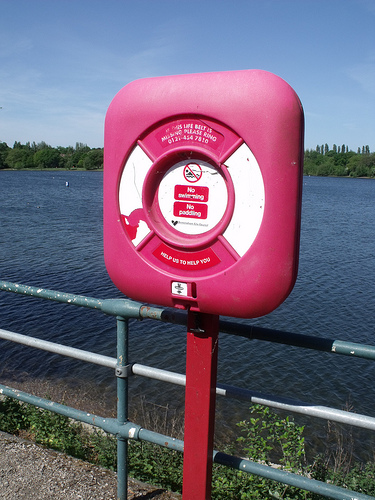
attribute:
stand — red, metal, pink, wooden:
[183, 311, 211, 496]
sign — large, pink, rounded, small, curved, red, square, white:
[103, 69, 302, 311]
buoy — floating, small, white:
[63, 179, 70, 189]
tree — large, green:
[323, 143, 329, 157]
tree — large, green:
[340, 143, 346, 156]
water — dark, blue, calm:
[2, 168, 373, 458]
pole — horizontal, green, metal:
[114, 296, 128, 499]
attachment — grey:
[101, 296, 144, 320]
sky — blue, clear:
[0, 0, 374, 150]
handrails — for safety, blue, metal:
[0, 277, 373, 499]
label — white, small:
[171, 280, 187, 297]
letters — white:
[156, 118, 220, 150]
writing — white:
[155, 251, 217, 267]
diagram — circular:
[115, 110, 266, 282]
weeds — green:
[233, 401, 312, 493]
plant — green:
[0, 396, 29, 434]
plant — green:
[26, 403, 80, 455]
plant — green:
[85, 432, 157, 475]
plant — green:
[313, 438, 374, 493]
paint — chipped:
[15, 284, 43, 296]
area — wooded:
[2, 141, 373, 178]